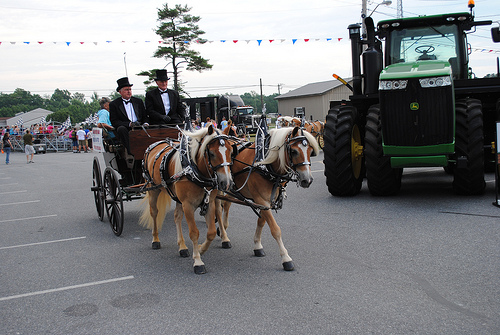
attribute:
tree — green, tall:
[140, 7, 230, 108]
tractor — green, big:
[317, 14, 499, 199]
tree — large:
[129, 2, 219, 87]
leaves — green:
[153, 0, 183, 18]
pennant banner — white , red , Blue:
[5, 32, 498, 62]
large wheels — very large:
[87, 160, 142, 242]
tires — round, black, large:
[321, 106, 398, 210]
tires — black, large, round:
[453, 94, 492, 194]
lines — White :
[3, 188, 138, 323]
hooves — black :
[142, 232, 207, 277]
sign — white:
[78, 122, 120, 171]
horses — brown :
[134, 112, 339, 299]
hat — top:
[152, 70, 170, 80]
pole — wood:
[255, 75, 265, 113]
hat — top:
[131, 43, 181, 83]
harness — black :
[151, 145, 183, 197]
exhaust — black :
[362, 15, 376, 48]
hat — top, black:
[113, 76, 135, 94]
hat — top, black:
[150, 69, 172, 81]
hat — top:
[114, 74, 131, 94]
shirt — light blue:
[92, 110, 117, 143]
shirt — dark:
[1, 135, 12, 145]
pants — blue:
[1, 143, 11, 171]